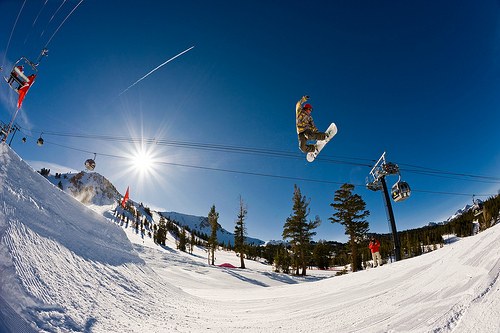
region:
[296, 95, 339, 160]
the skater is in mid air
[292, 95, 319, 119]
the skater has his arm raised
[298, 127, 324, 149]
the skater is wearing long pants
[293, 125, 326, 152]
the pants are black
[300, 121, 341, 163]
the skateboard is grey in color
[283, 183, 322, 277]
a pine tree is in the distance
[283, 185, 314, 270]
the tree is green in color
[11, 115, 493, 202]
cables above run along the snow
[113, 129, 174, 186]
the sun is in the sky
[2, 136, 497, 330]
the snow is white in color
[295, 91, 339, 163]
high flying skateboarder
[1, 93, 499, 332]
high flying skateboarder in half pipe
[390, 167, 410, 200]
ski lift gondola car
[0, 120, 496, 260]
gonda ski lift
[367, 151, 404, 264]
ski life tower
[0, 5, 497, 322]
sunny day with blue sky at ski resort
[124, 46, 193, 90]
jet contrail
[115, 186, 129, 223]
orange ski resort marker flag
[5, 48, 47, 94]
skier on chairlift chair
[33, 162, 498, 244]
snow covered mountains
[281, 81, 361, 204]
Snowboarder in the air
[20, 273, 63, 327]
Snow covering the ground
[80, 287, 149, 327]
Snow covering the ground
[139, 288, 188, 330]
Snow covering the ground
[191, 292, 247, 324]
Snow covering the ground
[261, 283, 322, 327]
Snow covering the ground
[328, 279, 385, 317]
Snow covering the ground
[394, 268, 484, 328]
Snow covering the ground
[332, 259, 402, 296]
Snow covering the ground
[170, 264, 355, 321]
Snow covering the ground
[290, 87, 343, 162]
a snowboarder in the sky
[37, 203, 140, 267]
shadow on the snow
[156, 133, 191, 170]
electrical lines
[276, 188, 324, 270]
trees on the snow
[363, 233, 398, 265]
a person standing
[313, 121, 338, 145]
a white snowboard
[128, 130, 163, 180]
the sun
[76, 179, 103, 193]
a mountain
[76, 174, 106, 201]
snow on the mountain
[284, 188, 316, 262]
a tall green tree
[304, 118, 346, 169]
White snowboard in the air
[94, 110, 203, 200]
Very bright sun shining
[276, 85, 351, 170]
Snowboarder doing a jump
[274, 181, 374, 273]
Pair of two evergreen trees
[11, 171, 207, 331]
Large ramp covered with snow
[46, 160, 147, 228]
Small mountain in the distance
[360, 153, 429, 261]
Snowlift with black pole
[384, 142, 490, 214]
Snowlift wires in the air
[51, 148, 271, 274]
Two mountains covered with snow in the distance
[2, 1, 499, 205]
Beautiful blue clear sky